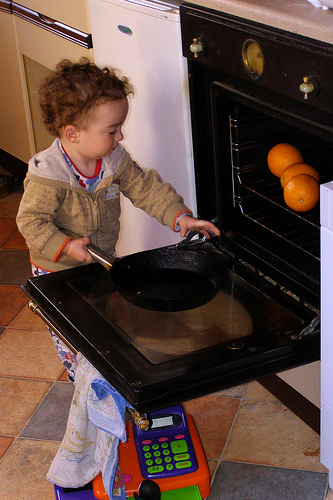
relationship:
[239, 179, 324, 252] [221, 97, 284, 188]
rack in oven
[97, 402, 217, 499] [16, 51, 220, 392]
toy belongs to child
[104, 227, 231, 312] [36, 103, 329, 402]
skillet on stove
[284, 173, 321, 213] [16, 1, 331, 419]
orange in stove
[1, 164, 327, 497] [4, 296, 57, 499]
floor has tiles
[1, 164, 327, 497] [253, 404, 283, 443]
floor seen part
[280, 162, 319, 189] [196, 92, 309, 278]
orange in oven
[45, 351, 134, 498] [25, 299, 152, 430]
blanket on handle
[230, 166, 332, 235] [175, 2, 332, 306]
rack in oven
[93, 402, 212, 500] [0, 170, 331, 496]
toy on ground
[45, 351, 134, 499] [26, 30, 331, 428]
blanket on oven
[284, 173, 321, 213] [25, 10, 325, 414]
orange inside oven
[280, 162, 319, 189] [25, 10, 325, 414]
orange inside oven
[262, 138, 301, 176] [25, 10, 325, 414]
orange inside oven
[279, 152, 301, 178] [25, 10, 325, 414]
orange inside oven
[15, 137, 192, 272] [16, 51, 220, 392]
brown jacket on child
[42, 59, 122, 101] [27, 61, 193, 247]
red hair on head of child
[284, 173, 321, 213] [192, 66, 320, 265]
orange in oven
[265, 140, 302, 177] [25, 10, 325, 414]
orange in oven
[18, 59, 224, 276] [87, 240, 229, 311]
child holds black pan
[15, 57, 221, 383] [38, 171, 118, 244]
child with brown jacket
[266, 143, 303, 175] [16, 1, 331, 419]
orange in stove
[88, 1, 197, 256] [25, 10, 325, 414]
fridge by oven